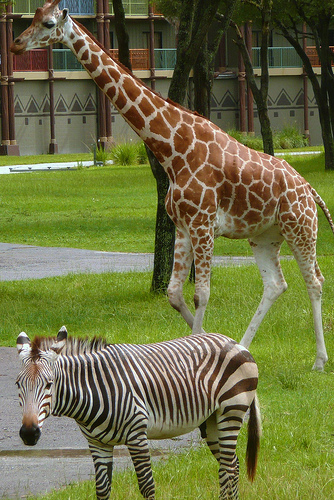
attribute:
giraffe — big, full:
[9, 0, 334, 379]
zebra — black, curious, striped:
[13, 324, 261, 500]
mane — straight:
[23, 332, 108, 359]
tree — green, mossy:
[208, 0, 291, 159]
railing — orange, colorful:
[104, 49, 150, 70]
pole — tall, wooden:
[0, 0, 18, 155]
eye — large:
[44, 380, 54, 390]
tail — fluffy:
[306, 183, 333, 227]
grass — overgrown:
[2, 152, 331, 496]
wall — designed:
[4, 70, 330, 155]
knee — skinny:
[188, 289, 212, 315]